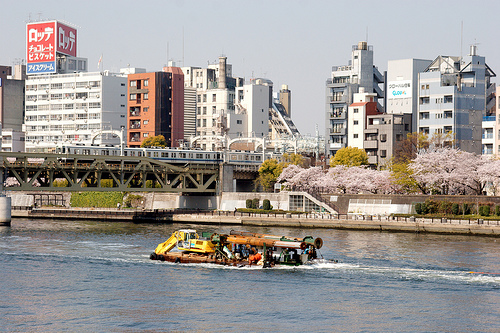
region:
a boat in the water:
[132, 175, 436, 293]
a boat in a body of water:
[154, 207, 339, 308]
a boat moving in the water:
[116, 205, 368, 328]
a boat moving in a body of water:
[167, 208, 359, 319]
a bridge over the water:
[4, 91, 287, 251]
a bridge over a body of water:
[51, 101, 365, 222]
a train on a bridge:
[47, 101, 303, 191]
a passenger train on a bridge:
[28, 118, 281, 207]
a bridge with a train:
[54, 129, 293, 191]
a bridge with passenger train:
[52, 118, 328, 178]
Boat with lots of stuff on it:
[157, 213, 321, 275]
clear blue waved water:
[67, 256, 236, 328]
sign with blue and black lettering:
[373, 63, 415, 101]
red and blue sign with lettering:
[23, 20, 83, 82]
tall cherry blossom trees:
[403, 145, 483, 205]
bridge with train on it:
[36, 130, 289, 187]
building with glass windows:
[273, 175, 346, 222]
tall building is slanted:
[255, 79, 307, 159]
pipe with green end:
[300, 227, 336, 255]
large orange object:
[246, 249, 263, 265]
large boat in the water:
[150, 223, 330, 271]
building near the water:
[358, 108, 411, 168]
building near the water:
[408, 19, 489, 157]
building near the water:
[384, 51, 438, 115]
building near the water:
[323, 36, 383, 161]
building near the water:
[344, 84, 383, 152]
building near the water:
[229, 75, 276, 141]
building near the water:
[20, 66, 130, 158]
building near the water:
[120, 64, 184, 147]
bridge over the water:
[0, 135, 271, 207]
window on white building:
[75, 80, 90, 89]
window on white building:
[87, 80, 99, 85]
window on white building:
[59, 81, 77, 90]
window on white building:
[48, 82, 63, 91]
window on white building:
[35, 80, 52, 90]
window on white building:
[86, 92, 100, 100]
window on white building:
[73, 92, 88, 101]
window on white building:
[88, 112, 100, 119]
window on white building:
[47, 112, 64, 120]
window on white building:
[25, 103, 37, 112]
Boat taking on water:
[140, 218, 340, 278]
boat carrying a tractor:
[145, 221, 217, 262]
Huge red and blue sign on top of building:
[19, 13, 84, 81]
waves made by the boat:
[300, 250, 497, 294]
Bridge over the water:
[3, 143, 246, 197]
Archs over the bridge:
[78, 120, 130, 165]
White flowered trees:
[270, 140, 498, 197]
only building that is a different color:
[120, 61, 187, 154]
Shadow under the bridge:
[146, 186, 232, 217]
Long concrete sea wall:
[6, 198, 498, 240]